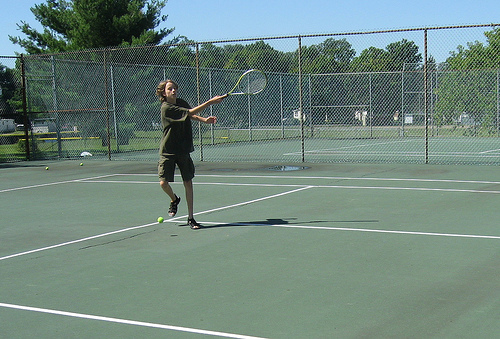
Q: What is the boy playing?
A: Tennis.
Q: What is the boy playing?
A: Tennis.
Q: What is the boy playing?
A: Tennis.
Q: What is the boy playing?
A: Tennis.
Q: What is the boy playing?
A: Tennis.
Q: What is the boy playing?
A: Tennis.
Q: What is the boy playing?
A: Tennis.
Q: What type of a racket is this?
A: A tennis racket.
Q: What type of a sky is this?
A: A blue sky.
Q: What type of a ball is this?
A: A yellow tennis ball.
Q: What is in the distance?
A: Large trees.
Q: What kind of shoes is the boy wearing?
A: Black shoes.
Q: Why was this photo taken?
A: For a magazine.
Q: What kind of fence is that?
A: A steel fence.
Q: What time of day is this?
A: Early afternoon.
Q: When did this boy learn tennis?
A: At age five.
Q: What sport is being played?
A: Tennis.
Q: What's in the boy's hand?
A: Racquet.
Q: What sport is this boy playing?
A: Tennis.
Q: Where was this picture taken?
A: Tennis court.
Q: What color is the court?
A: Green.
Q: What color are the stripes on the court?
A: White.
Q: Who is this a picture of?
A: A boy.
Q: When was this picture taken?
A: Daytime.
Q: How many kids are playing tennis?
A: One.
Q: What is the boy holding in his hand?
A: Tennis racket.